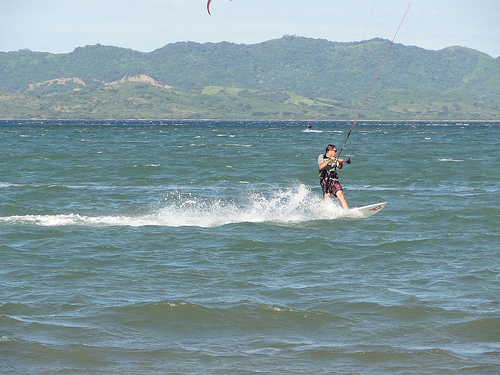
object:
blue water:
[1, 128, 499, 373]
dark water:
[4, 119, 496, 129]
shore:
[0, 95, 496, 117]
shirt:
[317, 153, 339, 177]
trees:
[0, 35, 500, 119]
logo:
[370, 206, 383, 211]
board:
[347, 201, 389, 221]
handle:
[330, 158, 341, 169]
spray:
[161, 176, 351, 229]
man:
[316, 144, 344, 211]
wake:
[0, 190, 325, 233]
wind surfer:
[317, 142, 348, 214]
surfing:
[221, 126, 404, 227]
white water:
[3, 183, 344, 233]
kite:
[201, 0, 219, 19]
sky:
[0, 0, 499, 54]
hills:
[0, 36, 499, 121]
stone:
[26, 72, 176, 92]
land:
[0, 35, 500, 124]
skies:
[340, 198, 391, 217]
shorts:
[320, 178, 344, 196]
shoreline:
[316, 106, 408, 127]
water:
[2, 118, 499, 370]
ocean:
[0, 126, 500, 372]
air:
[0, 0, 495, 375]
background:
[0, 3, 496, 127]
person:
[306, 123, 312, 132]